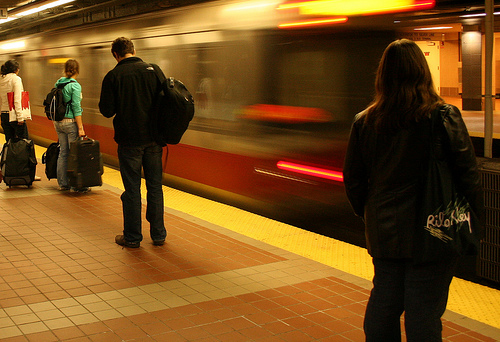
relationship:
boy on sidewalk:
[97, 33, 168, 249] [0, 132, 500, 339]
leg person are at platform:
[348, 32, 471, 339] [25, 247, 406, 337]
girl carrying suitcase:
[40, 49, 97, 203] [74, 132, 106, 193]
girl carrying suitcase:
[40, 49, 97, 203] [42, 75, 68, 120]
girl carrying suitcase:
[40, 49, 97, 203] [41, 138, 56, 183]